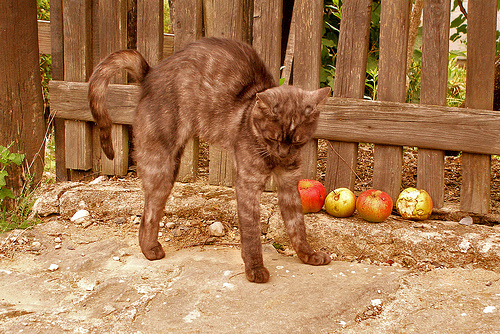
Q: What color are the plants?
A: Green.